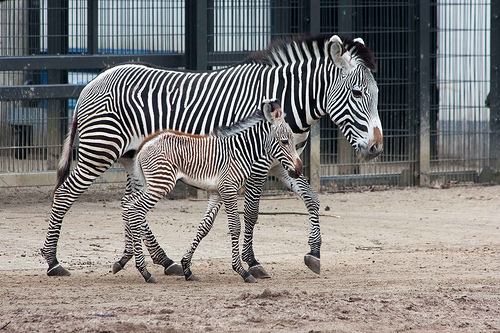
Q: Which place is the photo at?
A: It is at the pen.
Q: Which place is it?
A: It is a pen.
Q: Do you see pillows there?
A: No, there are no pillows.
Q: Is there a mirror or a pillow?
A: No, there are no pillows or mirrors.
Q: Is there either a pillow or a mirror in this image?
A: No, there are no pillows or mirrors.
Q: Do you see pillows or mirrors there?
A: No, there are no pillows or mirrors.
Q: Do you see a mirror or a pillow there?
A: No, there are no pillows or mirrors.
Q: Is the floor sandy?
A: Yes, the floor is sandy.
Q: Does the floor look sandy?
A: Yes, the floor is sandy.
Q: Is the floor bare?
A: No, the floor is sandy.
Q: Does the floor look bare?
A: No, the floor is sandy.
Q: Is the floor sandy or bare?
A: The floor is sandy.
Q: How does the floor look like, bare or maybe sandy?
A: The floor is sandy.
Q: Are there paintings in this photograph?
A: No, there are no paintings.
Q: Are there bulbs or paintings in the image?
A: No, there are no paintings or bulbs.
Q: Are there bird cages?
A: No, there are no bird cages.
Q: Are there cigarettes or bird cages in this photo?
A: No, there are no bird cages or cigarettes.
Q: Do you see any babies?
A: Yes, there is a baby.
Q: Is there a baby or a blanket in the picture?
A: Yes, there is a baby.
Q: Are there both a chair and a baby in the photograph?
A: No, there is a baby but no chairs.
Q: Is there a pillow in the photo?
A: No, there are no pillows.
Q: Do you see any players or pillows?
A: No, there are no pillows or players.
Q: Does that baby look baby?
A: Yes, the baby is a baby.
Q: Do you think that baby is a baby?
A: Yes, the baby is a baby.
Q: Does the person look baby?
A: Yes, the baby is a baby.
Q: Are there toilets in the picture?
A: No, there are no toilets.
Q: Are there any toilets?
A: No, there are no toilets.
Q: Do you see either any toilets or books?
A: No, there are no toilets or books.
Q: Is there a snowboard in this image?
A: No, there are no snowboards.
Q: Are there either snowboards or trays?
A: No, there are no snowboards or trays.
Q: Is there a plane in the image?
A: No, there are no airplanes.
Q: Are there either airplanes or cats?
A: No, there are no airplanes or cats.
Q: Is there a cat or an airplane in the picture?
A: No, there are no airplanes or cats.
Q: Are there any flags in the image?
A: No, there are no flags.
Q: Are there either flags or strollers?
A: No, there are no flags or strollers.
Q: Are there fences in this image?
A: Yes, there is a fence.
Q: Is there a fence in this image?
A: Yes, there is a fence.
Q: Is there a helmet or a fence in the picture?
A: Yes, there is a fence.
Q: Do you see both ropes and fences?
A: No, there is a fence but no ropes.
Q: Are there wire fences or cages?
A: Yes, there is a wire fence.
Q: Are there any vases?
A: No, there are no vases.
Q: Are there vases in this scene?
A: No, there are no vases.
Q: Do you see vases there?
A: No, there are no vases.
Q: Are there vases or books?
A: No, there are no vases or books.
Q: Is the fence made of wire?
A: Yes, the fence is made of wire.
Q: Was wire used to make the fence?
A: Yes, the fence is made of wire.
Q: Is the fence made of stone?
A: No, the fence is made of wire.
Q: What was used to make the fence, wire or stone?
A: The fence is made of wire.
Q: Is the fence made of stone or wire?
A: The fence is made of wire.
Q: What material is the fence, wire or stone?
A: The fence is made of wire.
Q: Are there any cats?
A: No, there are no cats.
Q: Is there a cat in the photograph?
A: No, there are no cats.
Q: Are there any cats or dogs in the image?
A: No, there are no cats or dogs.